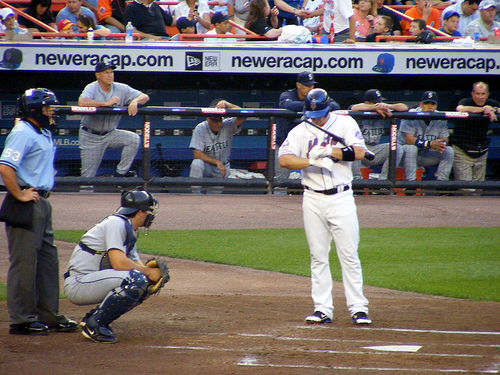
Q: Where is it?
A: This is at the field.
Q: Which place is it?
A: It is a field.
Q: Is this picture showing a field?
A: Yes, it is showing a field.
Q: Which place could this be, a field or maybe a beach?
A: It is a field.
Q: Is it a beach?
A: No, it is a field.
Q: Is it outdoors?
A: Yes, it is outdoors.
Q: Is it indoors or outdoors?
A: It is outdoors.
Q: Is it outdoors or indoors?
A: It is outdoors.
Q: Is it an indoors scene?
A: No, it is outdoors.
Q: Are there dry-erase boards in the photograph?
A: No, there are no dry-erase boards.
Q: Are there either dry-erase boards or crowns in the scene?
A: No, there are no dry-erase boards or crowns.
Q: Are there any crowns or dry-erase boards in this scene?
A: No, there are no dry-erase boards or crowns.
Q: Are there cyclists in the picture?
A: No, there are no cyclists.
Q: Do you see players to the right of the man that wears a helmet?
A: Yes, there is a player to the right of the man.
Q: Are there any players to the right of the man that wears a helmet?
A: Yes, there is a player to the right of the man.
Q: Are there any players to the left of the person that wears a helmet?
A: No, the player is to the right of the man.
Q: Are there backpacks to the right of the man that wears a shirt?
A: No, there is a player to the right of the man.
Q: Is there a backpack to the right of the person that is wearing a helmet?
A: No, there is a player to the right of the man.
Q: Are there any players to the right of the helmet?
A: Yes, there is a player to the right of the helmet.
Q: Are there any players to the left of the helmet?
A: No, the player is to the right of the helmet.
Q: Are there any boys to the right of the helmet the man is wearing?
A: No, there is a player to the right of the helmet.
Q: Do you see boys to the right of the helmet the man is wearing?
A: No, there is a player to the right of the helmet.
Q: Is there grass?
A: Yes, there is grass.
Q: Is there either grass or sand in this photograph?
A: Yes, there is grass.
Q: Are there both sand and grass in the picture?
A: No, there is grass but no sand.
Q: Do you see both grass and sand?
A: No, there is grass but no sand.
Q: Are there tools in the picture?
A: No, there are no tools.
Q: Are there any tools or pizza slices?
A: No, there are no tools or pizza slices.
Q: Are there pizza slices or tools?
A: No, there are no tools or pizza slices.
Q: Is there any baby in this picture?
A: No, there are no babies.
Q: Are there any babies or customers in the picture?
A: No, there are no babies or customers.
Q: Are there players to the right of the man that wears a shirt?
A: Yes, there are players to the right of the man.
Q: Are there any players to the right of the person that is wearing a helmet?
A: Yes, there are players to the right of the man.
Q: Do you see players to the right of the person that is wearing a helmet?
A: Yes, there are players to the right of the man.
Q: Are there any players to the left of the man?
A: No, the players are to the right of the man.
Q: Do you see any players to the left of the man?
A: No, the players are to the right of the man.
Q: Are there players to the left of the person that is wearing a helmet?
A: No, the players are to the right of the man.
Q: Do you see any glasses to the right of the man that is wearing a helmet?
A: No, there are players to the right of the man.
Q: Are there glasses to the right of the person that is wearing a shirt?
A: No, there are players to the right of the man.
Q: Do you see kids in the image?
A: No, there are no kids.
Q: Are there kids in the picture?
A: No, there are no kids.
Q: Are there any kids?
A: No, there are no kids.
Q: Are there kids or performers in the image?
A: No, there are no kids or performers.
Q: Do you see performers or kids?
A: No, there are no kids or performers.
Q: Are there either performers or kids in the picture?
A: No, there are no kids or performers.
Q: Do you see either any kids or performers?
A: No, there are no kids or performers.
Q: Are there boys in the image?
A: No, there are no boys.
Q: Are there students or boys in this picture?
A: No, there are no boys or students.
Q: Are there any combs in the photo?
A: No, there are no combs.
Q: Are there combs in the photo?
A: No, there are no combs.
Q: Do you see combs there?
A: No, there are no combs.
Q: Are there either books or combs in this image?
A: No, there are no combs or books.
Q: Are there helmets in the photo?
A: Yes, there is a helmet.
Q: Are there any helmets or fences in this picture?
A: Yes, there is a helmet.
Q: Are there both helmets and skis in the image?
A: No, there is a helmet but no skis.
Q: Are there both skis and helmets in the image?
A: No, there is a helmet but no skis.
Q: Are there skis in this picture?
A: No, there are no skis.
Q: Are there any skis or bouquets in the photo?
A: No, there are no skis or bouquets.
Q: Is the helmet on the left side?
A: Yes, the helmet is on the left of the image.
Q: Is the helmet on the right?
A: No, the helmet is on the left of the image.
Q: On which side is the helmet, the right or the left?
A: The helmet is on the left of the image.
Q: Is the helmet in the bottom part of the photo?
A: No, the helmet is in the top of the image.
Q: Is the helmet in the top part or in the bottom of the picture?
A: The helmet is in the top of the image.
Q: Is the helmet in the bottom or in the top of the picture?
A: The helmet is in the top of the image.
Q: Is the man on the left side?
A: Yes, the man is on the left of the image.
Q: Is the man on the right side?
A: No, the man is on the left of the image.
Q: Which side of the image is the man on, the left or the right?
A: The man is on the left of the image.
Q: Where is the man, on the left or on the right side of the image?
A: The man is on the left of the image.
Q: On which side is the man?
A: The man is on the left of the image.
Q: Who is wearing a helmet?
A: The man is wearing a helmet.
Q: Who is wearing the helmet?
A: The man is wearing a helmet.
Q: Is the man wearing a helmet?
A: Yes, the man is wearing a helmet.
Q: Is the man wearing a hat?
A: No, the man is wearing a helmet.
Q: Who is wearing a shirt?
A: The man is wearing a shirt.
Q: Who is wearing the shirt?
A: The man is wearing a shirt.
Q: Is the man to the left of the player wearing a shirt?
A: Yes, the man is wearing a shirt.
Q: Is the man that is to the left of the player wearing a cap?
A: No, the man is wearing a shirt.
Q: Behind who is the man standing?
A: The man is standing behind the player.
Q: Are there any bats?
A: Yes, there is a bat.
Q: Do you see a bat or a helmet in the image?
A: Yes, there is a bat.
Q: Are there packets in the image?
A: No, there are no packets.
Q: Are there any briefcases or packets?
A: No, there are no packets or briefcases.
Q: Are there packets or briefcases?
A: No, there are no packets or briefcases.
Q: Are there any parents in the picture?
A: No, there are no parents.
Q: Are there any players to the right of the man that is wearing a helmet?
A: Yes, there is a player to the right of the man.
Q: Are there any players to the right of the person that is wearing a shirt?
A: Yes, there is a player to the right of the man.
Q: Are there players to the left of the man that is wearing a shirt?
A: No, the player is to the right of the man.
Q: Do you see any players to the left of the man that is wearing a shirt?
A: No, the player is to the right of the man.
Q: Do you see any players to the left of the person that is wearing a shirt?
A: No, the player is to the right of the man.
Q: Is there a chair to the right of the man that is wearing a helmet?
A: No, there is a player to the right of the man.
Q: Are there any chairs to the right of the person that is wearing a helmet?
A: No, there is a player to the right of the man.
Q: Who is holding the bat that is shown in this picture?
A: The player is holding the bat.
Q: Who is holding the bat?
A: The player is holding the bat.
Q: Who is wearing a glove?
A: The player is wearing a glove.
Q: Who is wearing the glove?
A: The player is wearing a glove.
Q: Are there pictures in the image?
A: No, there are no pictures.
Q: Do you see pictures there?
A: No, there are no pictures.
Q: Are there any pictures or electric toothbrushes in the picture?
A: No, there are no pictures or electric toothbrushes.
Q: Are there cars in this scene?
A: No, there are no cars.